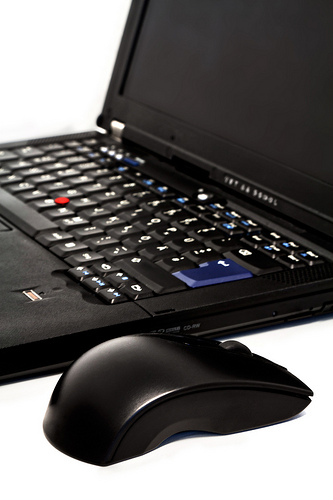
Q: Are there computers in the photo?
A: Yes, there is a computer.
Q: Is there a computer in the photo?
A: Yes, there is a computer.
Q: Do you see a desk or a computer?
A: Yes, there is a computer.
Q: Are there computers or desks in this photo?
A: Yes, there is a computer.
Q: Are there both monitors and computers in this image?
A: Yes, there are both a computer and a monitor.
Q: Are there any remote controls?
A: No, there are no remote controls.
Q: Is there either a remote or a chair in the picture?
A: No, there are no remote controls or chairs.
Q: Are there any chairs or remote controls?
A: No, there are no remote controls or chairs.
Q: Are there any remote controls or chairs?
A: No, there are no remote controls or chairs.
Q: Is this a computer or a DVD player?
A: This is a computer.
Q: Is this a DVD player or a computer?
A: This is a computer.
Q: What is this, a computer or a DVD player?
A: This is a computer.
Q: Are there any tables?
A: Yes, there is a table.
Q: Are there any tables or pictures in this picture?
A: Yes, there is a table.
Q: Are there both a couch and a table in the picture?
A: No, there is a table but no couches.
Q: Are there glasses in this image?
A: No, there are no glasses.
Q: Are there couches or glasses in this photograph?
A: No, there are no glasses or couches.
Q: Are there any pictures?
A: No, there are no pictures.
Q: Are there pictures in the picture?
A: No, there are no pictures.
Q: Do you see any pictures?
A: No, there are no pictures.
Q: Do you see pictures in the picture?
A: No, there are no pictures.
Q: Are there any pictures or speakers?
A: No, there are no pictures or speakers.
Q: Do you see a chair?
A: No, there are no chairs.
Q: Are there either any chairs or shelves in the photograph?
A: No, there are no chairs or shelves.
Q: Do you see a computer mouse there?
A: Yes, there is a computer mouse.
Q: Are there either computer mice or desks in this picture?
A: Yes, there is a computer mouse.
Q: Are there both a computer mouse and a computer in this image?
A: Yes, there are both a computer mouse and a computer.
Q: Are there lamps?
A: No, there are no lamps.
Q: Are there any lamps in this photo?
A: No, there are no lamps.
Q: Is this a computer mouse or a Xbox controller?
A: This is a computer mouse.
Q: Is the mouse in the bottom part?
A: Yes, the mouse is in the bottom of the image.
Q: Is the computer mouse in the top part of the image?
A: No, the computer mouse is in the bottom of the image.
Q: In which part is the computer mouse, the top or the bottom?
A: The computer mouse is in the bottom of the image.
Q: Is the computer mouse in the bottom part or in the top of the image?
A: The computer mouse is in the bottom of the image.